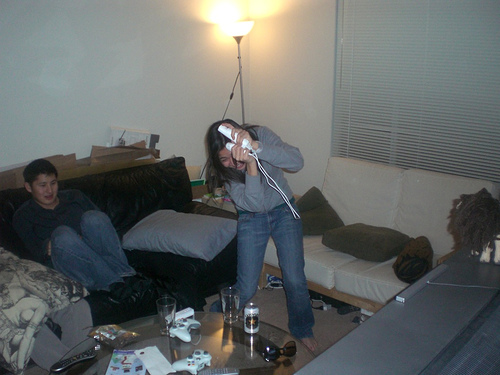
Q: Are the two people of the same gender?
A: No, they are both male and female.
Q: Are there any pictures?
A: No, there are no pictures.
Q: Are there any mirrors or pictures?
A: No, there are no pictures or mirrors.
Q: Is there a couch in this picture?
A: Yes, there is a couch.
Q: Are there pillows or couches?
A: Yes, there is a couch.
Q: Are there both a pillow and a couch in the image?
A: Yes, there are both a couch and a pillow.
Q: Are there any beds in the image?
A: No, there are no beds.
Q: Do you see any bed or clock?
A: No, there are no beds or clocks.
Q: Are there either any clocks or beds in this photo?
A: No, there are no beds or clocks.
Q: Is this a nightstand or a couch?
A: This is a couch.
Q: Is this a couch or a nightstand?
A: This is a couch.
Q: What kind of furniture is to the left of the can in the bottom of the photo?
A: The piece of furniture is a couch.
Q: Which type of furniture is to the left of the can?
A: The piece of furniture is a couch.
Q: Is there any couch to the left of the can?
A: Yes, there is a couch to the left of the can.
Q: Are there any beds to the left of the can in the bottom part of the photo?
A: No, there is a couch to the left of the can.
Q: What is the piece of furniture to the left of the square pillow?
A: The piece of furniture is a couch.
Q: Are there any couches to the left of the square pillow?
A: Yes, there is a couch to the left of the pillow.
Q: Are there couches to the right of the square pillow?
A: No, the couch is to the left of the pillow.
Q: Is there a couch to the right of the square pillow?
A: No, the couch is to the left of the pillow.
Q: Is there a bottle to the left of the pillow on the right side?
A: No, there is a couch to the left of the pillow.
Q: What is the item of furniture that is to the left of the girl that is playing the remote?
A: The piece of furniture is a couch.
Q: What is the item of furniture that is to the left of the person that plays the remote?
A: The piece of furniture is a couch.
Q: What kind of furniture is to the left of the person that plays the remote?
A: The piece of furniture is a couch.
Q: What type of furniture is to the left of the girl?
A: The piece of furniture is a couch.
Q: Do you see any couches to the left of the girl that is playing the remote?
A: Yes, there is a couch to the left of the girl.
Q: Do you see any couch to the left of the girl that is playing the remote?
A: Yes, there is a couch to the left of the girl.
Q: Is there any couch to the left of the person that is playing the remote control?
A: Yes, there is a couch to the left of the girl.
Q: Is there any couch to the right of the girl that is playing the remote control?
A: No, the couch is to the left of the girl.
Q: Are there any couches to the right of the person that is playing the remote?
A: No, the couch is to the left of the girl.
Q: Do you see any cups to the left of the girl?
A: No, there is a couch to the left of the girl.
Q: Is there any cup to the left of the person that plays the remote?
A: No, there is a couch to the left of the girl.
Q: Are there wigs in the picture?
A: No, there are no wigs.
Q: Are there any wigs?
A: No, there are no wigs.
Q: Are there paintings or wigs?
A: No, there are no wigs or paintings.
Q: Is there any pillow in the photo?
A: Yes, there is a pillow.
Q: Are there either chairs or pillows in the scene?
A: Yes, there is a pillow.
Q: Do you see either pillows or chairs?
A: Yes, there is a pillow.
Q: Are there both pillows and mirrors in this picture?
A: No, there is a pillow but no mirrors.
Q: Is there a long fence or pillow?
A: Yes, there is a long pillow.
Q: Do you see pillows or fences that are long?
A: Yes, the pillow is long.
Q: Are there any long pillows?
A: Yes, there is a long pillow.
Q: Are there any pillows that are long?
A: Yes, there is a pillow that is long.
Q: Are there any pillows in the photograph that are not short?
A: Yes, there is a long pillow.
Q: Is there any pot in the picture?
A: No, there are no pots.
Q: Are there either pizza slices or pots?
A: No, there are no pots or pizza slices.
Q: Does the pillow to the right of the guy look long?
A: Yes, the pillow is long.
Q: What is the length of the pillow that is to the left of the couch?
A: The pillow is long.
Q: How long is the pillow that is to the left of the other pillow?
A: The pillow is long.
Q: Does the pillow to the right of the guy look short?
A: No, the pillow is long.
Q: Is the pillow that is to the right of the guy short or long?
A: The pillow is long.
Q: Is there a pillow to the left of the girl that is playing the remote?
A: Yes, there is a pillow to the left of the girl.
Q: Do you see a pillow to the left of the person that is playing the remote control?
A: Yes, there is a pillow to the left of the girl.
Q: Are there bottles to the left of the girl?
A: No, there is a pillow to the left of the girl.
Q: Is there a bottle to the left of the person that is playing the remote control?
A: No, there is a pillow to the left of the girl.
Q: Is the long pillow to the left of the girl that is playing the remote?
A: Yes, the pillow is to the left of the girl.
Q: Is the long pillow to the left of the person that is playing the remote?
A: Yes, the pillow is to the left of the girl.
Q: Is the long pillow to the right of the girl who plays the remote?
A: No, the pillow is to the left of the girl.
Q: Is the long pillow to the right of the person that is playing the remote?
A: No, the pillow is to the left of the girl.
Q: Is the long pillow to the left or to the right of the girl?
A: The pillow is to the left of the girl.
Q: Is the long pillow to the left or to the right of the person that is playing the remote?
A: The pillow is to the left of the girl.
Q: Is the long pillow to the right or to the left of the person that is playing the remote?
A: The pillow is to the left of the girl.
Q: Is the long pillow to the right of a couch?
A: No, the pillow is to the left of a couch.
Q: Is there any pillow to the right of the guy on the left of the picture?
A: Yes, there is a pillow to the right of the guy.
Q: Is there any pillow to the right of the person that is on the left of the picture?
A: Yes, there is a pillow to the right of the guy.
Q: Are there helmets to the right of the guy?
A: No, there is a pillow to the right of the guy.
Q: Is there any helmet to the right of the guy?
A: No, there is a pillow to the right of the guy.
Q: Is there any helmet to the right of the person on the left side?
A: No, there is a pillow to the right of the guy.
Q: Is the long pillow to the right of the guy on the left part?
A: Yes, the pillow is to the right of the guy.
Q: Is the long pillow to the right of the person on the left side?
A: Yes, the pillow is to the right of the guy.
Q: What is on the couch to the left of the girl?
A: The pillow is on the couch.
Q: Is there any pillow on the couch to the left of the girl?
A: Yes, there is a pillow on the couch.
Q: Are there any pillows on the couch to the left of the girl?
A: Yes, there is a pillow on the couch.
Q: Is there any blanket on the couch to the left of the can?
A: No, there is a pillow on the couch.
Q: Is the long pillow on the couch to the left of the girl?
A: Yes, the pillow is on the couch.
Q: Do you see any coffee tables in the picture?
A: Yes, there is a coffee table.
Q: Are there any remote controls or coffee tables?
A: Yes, there is a coffee table.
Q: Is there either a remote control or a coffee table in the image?
A: Yes, there is a coffee table.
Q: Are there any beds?
A: No, there are no beds.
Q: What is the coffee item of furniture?
A: The piece of furniture is a coffee table.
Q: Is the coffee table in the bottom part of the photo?
A: Yes, the coffee table is in the bottom of the image.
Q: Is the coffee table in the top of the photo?
A: No, the coffee table is in the bottom of the image.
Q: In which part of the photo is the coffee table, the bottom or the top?
A: The coffee table is in the bottom of the image.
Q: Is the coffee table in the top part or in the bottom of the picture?
A: The coffee table is in the bottom of the image.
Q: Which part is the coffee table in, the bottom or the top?
A: The coffee table is in the bottom of the image.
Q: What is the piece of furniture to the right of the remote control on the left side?
A: The piece of furniture is a coffee table.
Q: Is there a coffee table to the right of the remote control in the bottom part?
A: Yes, there is a coffee table to the right of the remote.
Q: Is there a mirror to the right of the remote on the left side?
A: No, there is a coffee table to the right of the remote control.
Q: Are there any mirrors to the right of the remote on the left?
A: No, there is a coffee table to the right of the remote control.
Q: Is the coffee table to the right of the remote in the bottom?
A: Yes, the coffee table is to the right of the remote control.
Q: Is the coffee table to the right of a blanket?
A: No, the coffee table is to the right of the remote control.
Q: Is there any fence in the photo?
A: No, there are no fences.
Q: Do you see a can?
A: Yes, there is a can.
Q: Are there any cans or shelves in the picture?
A: Yes, there is a can.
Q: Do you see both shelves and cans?
A: No, there is a can but no shelves.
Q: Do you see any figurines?
A: No, there are no figurines.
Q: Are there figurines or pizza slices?
A: No, there are no figurines or pizza slices.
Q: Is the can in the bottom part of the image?
A: Yes, the can is in the bottom of the image.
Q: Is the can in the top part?
A: No, the can is in the bottom of the image.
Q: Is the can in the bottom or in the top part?
A: The can is in the bottom of the image.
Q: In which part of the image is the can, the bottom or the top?
A: The can is in the bottom of the image.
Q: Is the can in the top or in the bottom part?
A: The can is in the bottom of the image.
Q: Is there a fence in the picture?
A: No, there are no fences.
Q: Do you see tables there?
A: Yes, there is a table.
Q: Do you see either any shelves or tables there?
A: Yes, there is a table.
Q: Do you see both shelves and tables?
A: No, there is a table but no shelves.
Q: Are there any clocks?
A: No, there are no clocks.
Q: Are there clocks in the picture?
A: No, there are no clocks.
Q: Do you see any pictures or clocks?
A: No, there are no clocks or pictures.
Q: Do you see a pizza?
A: No, there are no pizzas.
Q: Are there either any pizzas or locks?
A: No, there are no pizzas or locks.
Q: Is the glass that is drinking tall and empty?
A: Yes, the glass is tall and empty.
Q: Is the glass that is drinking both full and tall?
A: No, the glass is tall but empty.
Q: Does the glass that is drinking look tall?
A: Yes, the glass is tall.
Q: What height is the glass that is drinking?
A: The glass is tall.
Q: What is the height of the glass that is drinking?
A: The glass is tall.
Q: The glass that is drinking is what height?
A: The glass is tall.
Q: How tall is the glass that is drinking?
A: The glass is tall.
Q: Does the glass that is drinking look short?
A: No, the glass is tall.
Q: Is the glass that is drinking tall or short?
A: The glass is tall.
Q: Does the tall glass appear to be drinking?
A: Yes, the glass is drinking.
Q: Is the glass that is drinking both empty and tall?
A: Yes, the glass is empty and tall.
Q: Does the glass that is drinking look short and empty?
A: No, the glass is empty but tall.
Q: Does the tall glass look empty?
A: Yes, the glass is empty.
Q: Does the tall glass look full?
A: No, the glass is empty.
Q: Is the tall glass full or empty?
A: The glass is empty.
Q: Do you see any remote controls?
A: Yes, there is a remote control.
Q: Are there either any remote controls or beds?
A: Yes, there is a remote control.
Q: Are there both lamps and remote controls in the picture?
A: Yes, there are both a remote control and a lamp.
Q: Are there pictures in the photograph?
A: No, there are no pictures.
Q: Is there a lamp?
A: Yes, there is a lamp.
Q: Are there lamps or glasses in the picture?
A: Yes, there is a lamp.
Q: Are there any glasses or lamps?
A: Yes, there is a lamp.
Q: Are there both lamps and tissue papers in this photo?
A: No, there is a lamp but no tissues.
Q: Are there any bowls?
A: No, there are no bowls.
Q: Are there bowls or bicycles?
A: No, there are no bowls or bicycles.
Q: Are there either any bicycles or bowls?
A: No, there are no bowls or bicycles.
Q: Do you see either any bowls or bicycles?
A: No, there are no bowls or bicycles.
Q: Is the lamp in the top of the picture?
A: Yes, the lamp is in the top of the image.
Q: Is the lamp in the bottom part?
A: No, the lamp is in the top of the image.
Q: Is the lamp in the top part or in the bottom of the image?
A: The lamp is in the top of the image.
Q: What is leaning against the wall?
A: The lamp is leaning against the wall.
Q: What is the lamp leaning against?
A: The lamp is leaning against the wall.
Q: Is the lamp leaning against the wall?
A: Yes, the lamp is leaning against the wall.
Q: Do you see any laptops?
A: No, there are no laptops.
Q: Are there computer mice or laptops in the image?
A: No, there are no laptops or computer mice.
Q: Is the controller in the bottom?
A: Yes, the controller is in the bottom of the image.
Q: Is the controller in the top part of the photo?
A: No, the controller is in the bottom of the image.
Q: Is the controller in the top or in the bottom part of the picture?
A: The controller is in the bottom of the image.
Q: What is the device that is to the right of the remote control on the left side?
A: The device is a controller.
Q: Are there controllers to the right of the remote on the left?
A: Yes, there is a controller to the right of the remote.